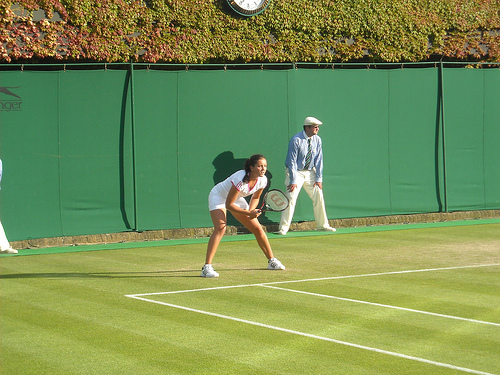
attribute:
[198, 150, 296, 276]
woman — playing, bent over, ready, dressed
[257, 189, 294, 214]
racquet — black, red, wilson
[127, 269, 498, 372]
lines — painted, white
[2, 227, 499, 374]
tennis court — lush, green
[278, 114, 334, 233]
man — well dressed, watching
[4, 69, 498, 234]
canvas — green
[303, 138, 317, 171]
tie — green, striped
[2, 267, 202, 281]
shadow — elongated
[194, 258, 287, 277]
shoes — white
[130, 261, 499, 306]
line — white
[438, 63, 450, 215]
pole — metal, green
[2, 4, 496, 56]
ivy — green, large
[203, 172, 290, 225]
gear — white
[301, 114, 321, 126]
hat — white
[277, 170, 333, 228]
pants — white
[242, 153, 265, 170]
hair — brown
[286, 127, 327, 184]
shirt — blue